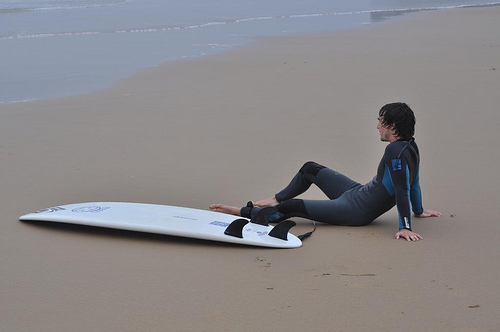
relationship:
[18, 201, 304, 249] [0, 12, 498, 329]
board on sand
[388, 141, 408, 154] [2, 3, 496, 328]
shoulder resting on beach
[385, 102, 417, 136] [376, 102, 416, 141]
hair on head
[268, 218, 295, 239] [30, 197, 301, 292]
fins on surfboard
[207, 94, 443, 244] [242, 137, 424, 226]
man wearing wet suit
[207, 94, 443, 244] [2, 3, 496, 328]
man sitting on beach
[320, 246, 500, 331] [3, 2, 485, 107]
ground looking at water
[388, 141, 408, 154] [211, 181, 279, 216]
shoulder has feet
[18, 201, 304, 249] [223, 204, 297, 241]
board has skegs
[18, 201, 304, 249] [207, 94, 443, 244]
board tethered to man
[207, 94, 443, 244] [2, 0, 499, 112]
man looking at sea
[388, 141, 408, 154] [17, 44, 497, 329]
shoulder on beach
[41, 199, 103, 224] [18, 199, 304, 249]
marking on board